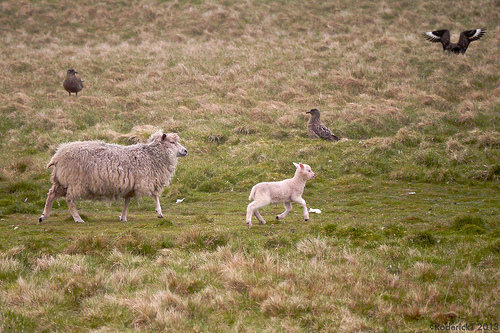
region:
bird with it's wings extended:
[416, 12, 487, 62]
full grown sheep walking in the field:
[14, 126, 201, 233]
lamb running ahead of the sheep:
[229, 152, 322, 229]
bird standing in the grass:
[61, 63, 93, 98]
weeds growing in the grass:
[446, 211, 483, 234]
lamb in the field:
[240, 159, 331, 219]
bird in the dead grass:
[297, 105, 341, 145]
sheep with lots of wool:
[34, 130, 189, 210]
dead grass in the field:
[230, 250, 387, 302]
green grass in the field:
[345, 186, 399, 208]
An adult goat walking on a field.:
[37, 126, 189, 224]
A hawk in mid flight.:
[418, 26, 486, 56]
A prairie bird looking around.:
[302, 108, 346, 146]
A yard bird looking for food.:
[62, 63, 89, 102]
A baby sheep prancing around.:
[244, 164, 318, 229]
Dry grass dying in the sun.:
[157, 258, 329, 308]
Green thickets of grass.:
[340, 179, 494, 233]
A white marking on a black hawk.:
[470, 26, 485, 41]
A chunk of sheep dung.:
[429, 306, 459, 331]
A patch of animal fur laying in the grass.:
[404, 186, 416, 200]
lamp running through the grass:
[241, 153, 323, 218]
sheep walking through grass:
[38, 122, 188, 222]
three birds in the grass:
[54, 20, 486, 144]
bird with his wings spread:
[420, 15, 485, 55]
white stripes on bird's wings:
[417, 23, 489, 43]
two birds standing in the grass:
[62, 67, 333, 145]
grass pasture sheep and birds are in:
[6, 3, 483, 315]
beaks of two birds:
[75, 64, 311, 129]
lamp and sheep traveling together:
[30, 124, 320, 229]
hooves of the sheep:
[36, 213, 171, 227]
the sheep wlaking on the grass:
[39, 126, 192, 234]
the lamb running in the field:
[236, 151, 316, 227]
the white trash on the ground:
[304, 203, 325, 218]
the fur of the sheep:
[53, 143, 176, 202]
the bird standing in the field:
[52, 56, 91, 111]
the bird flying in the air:
[420, 24, 489, 59]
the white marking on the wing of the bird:
[423, 27, 443, 44]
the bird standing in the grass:
[299, 103, 351, 152]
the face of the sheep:
[161, 132, 191, 161]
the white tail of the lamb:
[244, 186, 264, 203]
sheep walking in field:
[28, 74, 376, 288]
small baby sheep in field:
[220, 145, 347, 238]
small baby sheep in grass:
[237, 154, 322, 236]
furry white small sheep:
[237, 159, 323, 234]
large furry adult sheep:
[9, 120, 201, 250]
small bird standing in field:
[295, 99, 344, 154]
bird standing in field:
[40, 49, 100, 99]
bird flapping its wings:
[383, 13, 485, 85]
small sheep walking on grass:
[235, 145, 324, 234]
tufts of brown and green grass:
[182, 254, 279, 301]